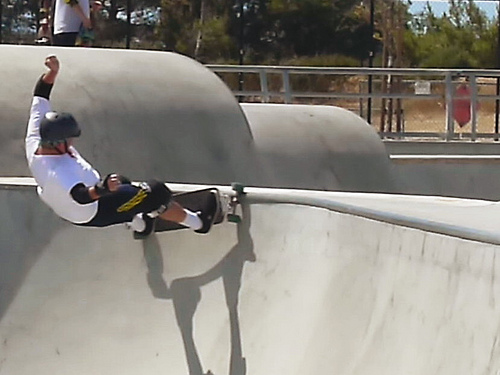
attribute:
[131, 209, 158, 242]
shoe — black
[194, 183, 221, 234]
shoe — black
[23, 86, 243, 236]
man — sideways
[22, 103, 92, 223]
shirt — white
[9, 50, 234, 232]
guy — one